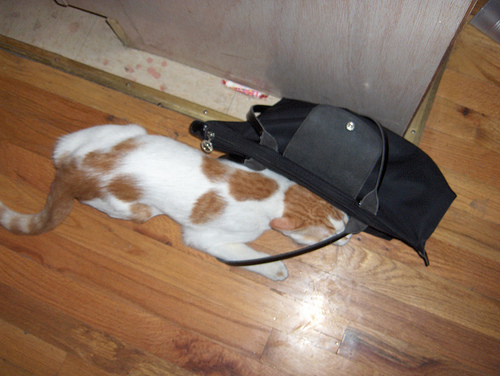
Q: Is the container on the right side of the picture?
A: Yes, the container is on the right of the image.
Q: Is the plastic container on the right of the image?
A: Yes, the container is on the right of the image.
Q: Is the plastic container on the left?
A: No, the container is on the right of the image.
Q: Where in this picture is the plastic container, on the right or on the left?
A: The container is on the right of the image.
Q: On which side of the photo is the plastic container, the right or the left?
A: The container is on the right of the image.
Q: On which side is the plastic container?
A: The container is on the right of the image.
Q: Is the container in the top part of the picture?
A: Yes, the container is in the top of the image.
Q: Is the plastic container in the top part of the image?
A: Yes, the container is in the top of the image.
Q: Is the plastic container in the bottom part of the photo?
A: No, the container is in the top of the image.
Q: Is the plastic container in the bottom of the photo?
A: No, the container is in the top of the image.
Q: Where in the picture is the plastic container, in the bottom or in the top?
A: The container is in the top of the image.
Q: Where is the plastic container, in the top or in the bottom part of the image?
A: The container is in the top of the image.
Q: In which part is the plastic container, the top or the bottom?
A: The container is in the top of the image.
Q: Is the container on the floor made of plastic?
A: Yes, the container is made of plastic.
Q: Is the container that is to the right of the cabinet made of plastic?
A: Yes, the container is made of plastic.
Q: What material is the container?
A: The container is made of plastic.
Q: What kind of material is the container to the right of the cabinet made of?
A: The container is made of plastic.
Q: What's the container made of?
A: The container is made of plastic.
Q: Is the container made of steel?
A: No, the container is made of plastic.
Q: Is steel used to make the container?
A: No, the container is made of plastic.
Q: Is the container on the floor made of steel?
A: No, the container is made of plastic.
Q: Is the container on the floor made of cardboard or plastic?
A: The container is made of plastic.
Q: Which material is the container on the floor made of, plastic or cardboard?
A: The container is made of plastic.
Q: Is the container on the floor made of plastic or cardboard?
A: The container is made of plastic.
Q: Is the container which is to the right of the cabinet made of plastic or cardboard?
A: The container is made of plastic.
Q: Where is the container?
A: The container is on the floor.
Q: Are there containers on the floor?
A: Yes, there is a container on the floor.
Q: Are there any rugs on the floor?
A: No, there is a container on the floor.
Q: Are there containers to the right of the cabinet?
A: Yes, there is a container to the right of the cabinet.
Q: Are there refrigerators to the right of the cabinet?
A: No, there is a container to the right of the cabinet.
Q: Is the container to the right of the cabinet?
A: Yes, the container is to the right of the cabinet.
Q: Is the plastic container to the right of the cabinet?
A: Yes, the container is to the right of the cabinet.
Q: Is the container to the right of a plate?
A: No, the container is to the right of the cabinet.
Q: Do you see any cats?
A: Yes, there is a cat.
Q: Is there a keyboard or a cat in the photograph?
A: Yes, there is a cat.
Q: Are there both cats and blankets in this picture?
A: No, there is a cat but no blankets.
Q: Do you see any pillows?
A: No, there are no pillows.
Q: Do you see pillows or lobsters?
A: No, there are no pillows or lobsters.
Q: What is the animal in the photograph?
A: The animal is a cat.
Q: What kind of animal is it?
A: The animal is a cat.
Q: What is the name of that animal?
A: This is a cat.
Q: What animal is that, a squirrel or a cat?
A: This is a cat.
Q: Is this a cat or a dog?
A: This is a cat.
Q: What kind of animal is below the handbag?
A: The animal is a cat.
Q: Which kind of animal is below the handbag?
A: The animal is a cat.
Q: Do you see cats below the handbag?
A: Yes, there is a cat below the handbag.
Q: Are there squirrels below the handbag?
A: No, there is a cat below the handbag.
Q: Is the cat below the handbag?
A: Yes, the cat is below the handbag.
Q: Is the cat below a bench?
A: No, the cat is below the handbag.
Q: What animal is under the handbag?
A: The cat is under the handbag.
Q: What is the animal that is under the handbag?
A: The animal is a cat.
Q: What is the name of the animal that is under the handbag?
A: The animal is a cat.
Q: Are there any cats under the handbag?
A: Yes, there is a cat under the handbag.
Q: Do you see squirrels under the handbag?
A: No, there is a cat under the handbag.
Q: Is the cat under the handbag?
A: Yes, the cat is under the handbag.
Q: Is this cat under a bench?
A: No, the cat is under the handbag.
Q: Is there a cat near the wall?
A: Yes, there is a cat near the wall.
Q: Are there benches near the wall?
A: No, there is a cat near the wall.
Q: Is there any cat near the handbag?
A: Yes, there is a cat near the handbag.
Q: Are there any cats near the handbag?
A: Yes, there is a cat near the handbag.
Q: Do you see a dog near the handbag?
A: No, there is a cat near the handbag.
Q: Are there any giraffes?
A: No, there are no giraffes.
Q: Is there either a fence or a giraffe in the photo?
A: No, there are no giraffes or fences.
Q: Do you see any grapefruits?
A: No, there are no grapefruits.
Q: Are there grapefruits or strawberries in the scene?
A: No, there are no grapefruits or strawberries.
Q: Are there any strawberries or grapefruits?
A: No, there are no grapefruits or strawberries.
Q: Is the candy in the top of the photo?
A: Yes, the candy is in the top of the image.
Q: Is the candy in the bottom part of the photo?
A: No, the candy is in the top of the image.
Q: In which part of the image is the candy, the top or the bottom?
A: The candy is in the top of the image.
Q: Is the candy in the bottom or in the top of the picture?
A: The candy is in the top of the image.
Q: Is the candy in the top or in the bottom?
A: The candy is in the top of the image.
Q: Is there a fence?
A: No, there are no fences.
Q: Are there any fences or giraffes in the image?
A: No, there are no fences or giraffes.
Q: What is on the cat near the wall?
A: The spots are on the cat.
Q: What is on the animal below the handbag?
A: The spots are on the cat.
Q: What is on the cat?
A: The spots are on the cat.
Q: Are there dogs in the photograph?
A: No, there are no dogs.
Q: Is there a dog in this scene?
A: No, there are no dogs.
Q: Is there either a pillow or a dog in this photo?
A: No, there are no dogs or pillows.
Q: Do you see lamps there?
A: No, there are no lamps.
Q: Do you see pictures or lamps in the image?
A: No, there are no lamps or pictures.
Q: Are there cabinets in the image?
A: Yes, there is a cabinet.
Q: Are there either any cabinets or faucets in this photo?
A: Yes, there is a cabinet.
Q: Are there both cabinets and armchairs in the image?
A: No, there is a cabinet but no armchairs.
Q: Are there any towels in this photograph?
A: No, there are no towels.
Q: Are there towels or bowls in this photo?
A: No, there are no towels or bowls.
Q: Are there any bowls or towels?
A: No, there are no towels or bowls.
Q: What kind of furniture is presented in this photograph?
A: The furniture is a cabinet.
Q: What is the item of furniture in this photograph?
A: The piece of furniture is a cabinet.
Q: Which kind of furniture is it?
A: The piece of furniture is a cabinet.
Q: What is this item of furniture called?
A: This is a cabinet.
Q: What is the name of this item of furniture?
A: This is a cabinet.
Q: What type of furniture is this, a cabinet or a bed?
A: This is a cabinet.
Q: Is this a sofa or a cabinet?
A: This is a cabinet.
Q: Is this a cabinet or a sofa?
A: This is a cabinet.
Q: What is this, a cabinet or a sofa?
A: This is a cabinet.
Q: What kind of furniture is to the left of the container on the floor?
A: The piece of furniture is a cabinet.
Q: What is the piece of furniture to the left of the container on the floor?
A: The piece of furniture is a cabinet.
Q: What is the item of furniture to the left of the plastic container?
A: The piece of furniture is a cabinet.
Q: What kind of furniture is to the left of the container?
A: The piece of furniture is a cabinet.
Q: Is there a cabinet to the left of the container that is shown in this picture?
A: Yes, there is a cabinet to the left of the container.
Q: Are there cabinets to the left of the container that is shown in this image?
A: Yes, there is a cabinet to the left of the container.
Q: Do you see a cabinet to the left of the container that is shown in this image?
A: Yes, there is a cabinet to the left of the container.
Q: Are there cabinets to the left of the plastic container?
A: Yes, there is a cabinet to the left of the container.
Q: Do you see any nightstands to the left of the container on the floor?
A: No, there is a cabinet to the left of the container.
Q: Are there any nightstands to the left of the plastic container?
A: No, there is a cabinet to the left of the container.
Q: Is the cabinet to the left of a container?
A: Yes, the cabinet is to the left of a container.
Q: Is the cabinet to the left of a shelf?
A: No, the cabinet is to the left of a container.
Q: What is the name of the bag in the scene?
A: The bag is a handbag.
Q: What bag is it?
A: The bag is a handbag.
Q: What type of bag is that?
A: This is a handbag.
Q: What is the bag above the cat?
A: The bag is a handbag.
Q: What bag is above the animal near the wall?
A: The bag is a handbag.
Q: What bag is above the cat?
A: The bag is a handbag.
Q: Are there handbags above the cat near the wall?
A: Yes, there is a handbag above the cat.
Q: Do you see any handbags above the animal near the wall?
A: Yes, there is a handbag above the cat.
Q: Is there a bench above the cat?
A: No, there is a handbag above the cat.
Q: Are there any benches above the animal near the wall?
A: No, there is a handbag above the cat.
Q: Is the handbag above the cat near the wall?
A: Yes, the handbag is above the cat.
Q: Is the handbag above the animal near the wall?
A: Yes, the handbag is above the cat.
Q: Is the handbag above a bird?
A: No, the handbag is above the cat.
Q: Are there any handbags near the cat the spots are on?
A: Yes, there is a handbag near the cat.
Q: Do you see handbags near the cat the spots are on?
A: Yes, there is a handbag near the cat.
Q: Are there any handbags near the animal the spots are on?
A: Yes, there is a handbag near the cat.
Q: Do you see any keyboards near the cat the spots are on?
A: No, there is a handbag near the cat.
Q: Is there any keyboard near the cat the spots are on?
A: No, there is a handbag near the cat.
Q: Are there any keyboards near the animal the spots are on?
A: No, there is a handbag near the cat.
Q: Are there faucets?
A: No, there are no faucets.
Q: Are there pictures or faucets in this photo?
A: No, there are no faucets or pictures.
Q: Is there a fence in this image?
A: No, there are no fences.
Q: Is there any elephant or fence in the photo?
A: No, there are no fences or elephants.